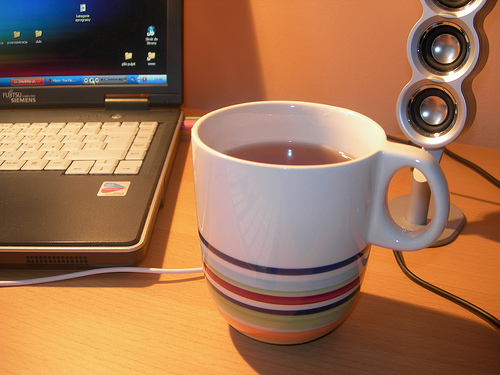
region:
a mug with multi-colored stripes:
[184, 107, 441, 356]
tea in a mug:
[205, 88, 367, 167]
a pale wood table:
[1, 109, 498, 374]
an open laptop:
[5, 1, 176, 263]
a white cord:
[0, 258, 204, 299]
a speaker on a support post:
[372, 6, 474, 247]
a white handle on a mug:
[372, 141, 458, 260]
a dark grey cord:
[386, 247, 497, 334]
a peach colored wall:
[183, 2, 496, 151]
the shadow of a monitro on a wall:
[165, 6, 275, 137]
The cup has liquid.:
[179, 94, 435, 350]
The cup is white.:
[184, 107, 453, 334]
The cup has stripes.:
[200, 94, 444, 341]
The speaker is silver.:
[416, 7, 482, 237]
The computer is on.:
[7, 8, 212, 147]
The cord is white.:
[23, 255, 196, 304]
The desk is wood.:
[53, 299, 218, 372]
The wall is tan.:
[215, 17, 393, 104]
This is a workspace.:
[9, 10, 492, 368]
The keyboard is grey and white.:
[3, 102, 169, 294]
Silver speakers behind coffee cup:
[390, 6, 497, 151]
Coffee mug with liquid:
[182, 99, 461, 348]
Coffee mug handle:
[374, 138, 459, 262]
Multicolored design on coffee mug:
[190, 240, 377, 340]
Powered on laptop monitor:
[0, 0, 185, 107]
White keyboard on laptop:
[0, 114, 162, 178]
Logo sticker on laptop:
[96, 178, 131, 197]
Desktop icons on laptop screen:
[1, 5, 167, 72]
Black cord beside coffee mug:
[383, 250, 497, 327]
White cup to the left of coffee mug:
[1, 262, 210, 292]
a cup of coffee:
[142, 82, 452, 367]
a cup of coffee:
[162, 92, 337, 232]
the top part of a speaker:
[418, 0, 482, 19]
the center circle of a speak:
[414, 19, 473, 88]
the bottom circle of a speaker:
[402, 79, 469, 143]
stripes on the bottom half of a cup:
[197, 231, 365, 338]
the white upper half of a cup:
[205, 154, 353, 256]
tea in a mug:
[231, 137, 342, 169]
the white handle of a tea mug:
[384, 143, 446, 259]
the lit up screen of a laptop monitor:
[7, 5, 173, 90]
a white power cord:
[4, 261, 199, 283]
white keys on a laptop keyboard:
[10, 119, 162, 176]